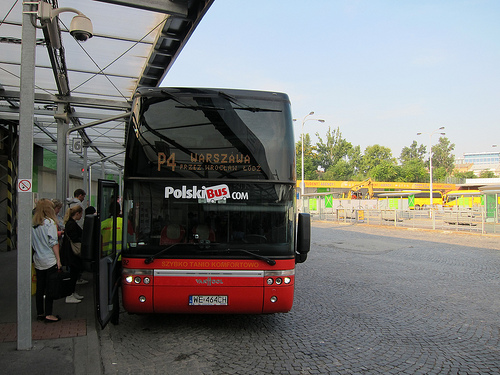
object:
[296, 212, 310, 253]
mirror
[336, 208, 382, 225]
chair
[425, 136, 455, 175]
trees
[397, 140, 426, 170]
trees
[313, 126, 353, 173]
trees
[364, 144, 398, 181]
trees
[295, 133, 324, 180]
trees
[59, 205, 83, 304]
woman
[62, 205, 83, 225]
hair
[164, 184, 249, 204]
logo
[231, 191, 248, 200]
letters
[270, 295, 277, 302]
light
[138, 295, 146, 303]
light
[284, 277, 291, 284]
light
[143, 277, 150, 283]
light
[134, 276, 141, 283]
light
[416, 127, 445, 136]
light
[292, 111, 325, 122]
light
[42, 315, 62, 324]
shoes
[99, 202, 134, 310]
person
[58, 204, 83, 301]
people bus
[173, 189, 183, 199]
o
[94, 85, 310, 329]
bus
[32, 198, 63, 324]
girl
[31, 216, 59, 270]
white shirt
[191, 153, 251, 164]
letter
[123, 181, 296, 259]
window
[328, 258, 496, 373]
cobble stones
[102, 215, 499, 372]
street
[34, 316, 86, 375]
platform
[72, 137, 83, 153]
sign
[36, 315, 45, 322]
shoes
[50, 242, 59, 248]
elbow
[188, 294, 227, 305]
license plate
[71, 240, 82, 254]
tan bag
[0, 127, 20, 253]
column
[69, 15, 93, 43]
light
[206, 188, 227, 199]
word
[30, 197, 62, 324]
woman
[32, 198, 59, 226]
blonde hair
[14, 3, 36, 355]
pole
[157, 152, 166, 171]
p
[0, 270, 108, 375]
concrete